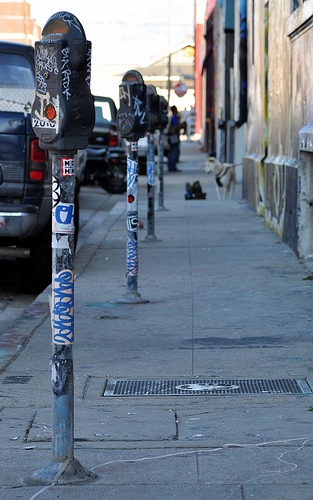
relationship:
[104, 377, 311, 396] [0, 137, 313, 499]
grate on ground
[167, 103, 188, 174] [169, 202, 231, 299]
person on sidewalk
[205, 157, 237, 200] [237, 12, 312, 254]
dog walking next to building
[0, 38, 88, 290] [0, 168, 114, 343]
car parked at roadside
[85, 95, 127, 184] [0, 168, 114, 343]
car parked at roadside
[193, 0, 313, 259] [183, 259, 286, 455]
building along sidewalk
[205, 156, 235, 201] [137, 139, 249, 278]
dog on sidewalk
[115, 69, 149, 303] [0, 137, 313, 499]
meter on ground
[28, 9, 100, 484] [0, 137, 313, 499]
meter on ground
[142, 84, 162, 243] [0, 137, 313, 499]
meter on ground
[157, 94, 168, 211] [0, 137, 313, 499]
meter on ground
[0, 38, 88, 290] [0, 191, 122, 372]
car parked near curb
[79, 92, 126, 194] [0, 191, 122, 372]
car parked near curb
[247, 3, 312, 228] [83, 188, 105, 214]
building beside road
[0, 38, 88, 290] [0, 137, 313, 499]
car parked beside ground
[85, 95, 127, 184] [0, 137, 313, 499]
car parked beside ground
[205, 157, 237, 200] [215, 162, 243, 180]
dog wearing a harness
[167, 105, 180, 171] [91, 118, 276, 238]
person standing on sidewalk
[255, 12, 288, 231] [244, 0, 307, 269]
graffitti on wall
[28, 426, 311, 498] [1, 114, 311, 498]
string on ground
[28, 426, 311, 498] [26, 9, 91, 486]
string beside meter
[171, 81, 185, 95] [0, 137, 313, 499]
sign at end of ground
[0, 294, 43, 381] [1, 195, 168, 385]
graffiti on curb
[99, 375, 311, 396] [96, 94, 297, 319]
grate in sidewalk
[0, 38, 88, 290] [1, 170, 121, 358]
car parked on street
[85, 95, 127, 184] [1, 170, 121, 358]
car parked on street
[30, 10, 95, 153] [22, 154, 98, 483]
parking meters are on poles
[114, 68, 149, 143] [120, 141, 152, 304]
parking meters are on poles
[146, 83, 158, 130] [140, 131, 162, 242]
parking meters are on poles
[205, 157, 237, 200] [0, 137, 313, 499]
dog standing on ground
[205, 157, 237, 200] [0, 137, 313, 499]
dog on ground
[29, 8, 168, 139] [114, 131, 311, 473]
parking meters on sidewalk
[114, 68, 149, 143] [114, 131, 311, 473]
parking meters on sidewalk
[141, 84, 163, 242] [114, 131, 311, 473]
meter on sidewalk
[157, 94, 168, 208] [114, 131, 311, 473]
parking meters on sidewalk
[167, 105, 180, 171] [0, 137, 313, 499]
person standing on ground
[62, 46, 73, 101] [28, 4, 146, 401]
graffiti on parking meter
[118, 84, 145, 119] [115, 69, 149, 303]
graffiti on meter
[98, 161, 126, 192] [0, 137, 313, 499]
bag on ground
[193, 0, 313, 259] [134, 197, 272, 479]
building along sidewalk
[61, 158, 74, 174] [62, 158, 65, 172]
letterig on background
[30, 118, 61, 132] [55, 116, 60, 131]
numbers on background